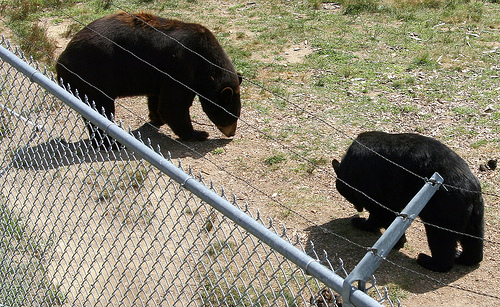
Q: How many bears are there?
A: Two.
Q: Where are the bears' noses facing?
A: Toward the ground.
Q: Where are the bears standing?
A: In the dirt.